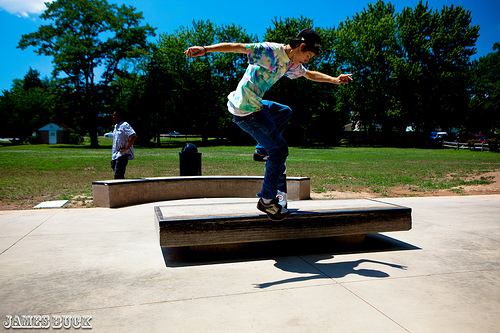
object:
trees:
[0, 0, 499, 151]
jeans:
[229, 99, 290, 200]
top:
[181, 143, 198, 153]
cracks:
[299, 260, 412, 332]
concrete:
[91, 175, 311, 210]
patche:
[387, 184, 418, 196]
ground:
[0, 134, 499, 333]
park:
[0, 0, 499, 333]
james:
[2, 313, 42, 331]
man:
[106, 109, 137, 180]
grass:
[0, 136, 499, 213]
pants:
[110, 156, 128, 179]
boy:
[182, 28, 351, 223]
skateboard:
[264, 156, 289, 222]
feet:
[252, 146, 292, 221]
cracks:
[0, 205, 66, 280]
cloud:
[0, 0, 51, 21]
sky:
[0, 0, 498, 101]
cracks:
[175, 276, 332, 310]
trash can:
[179, 143, 203, 176]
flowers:
[347, 129, 434, 138]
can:
[179, 143, 202, 176]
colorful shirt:
[225, 41, 307, 117]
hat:
[287, 28, 322, 50]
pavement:
[0, 194, 499, 332]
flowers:
[73, 196, 88, 205]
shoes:
[257, 197, 292, 221]